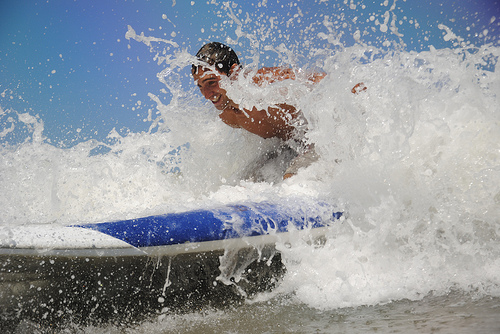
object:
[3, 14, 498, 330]
water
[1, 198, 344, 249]
board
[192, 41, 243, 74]
hair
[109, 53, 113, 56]
drop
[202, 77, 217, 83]
eyebrow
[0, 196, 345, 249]
surfboard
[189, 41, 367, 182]
man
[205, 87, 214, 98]
nose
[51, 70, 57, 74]
water drop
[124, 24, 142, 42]
drop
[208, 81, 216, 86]
eye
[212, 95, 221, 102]
teeth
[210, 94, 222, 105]
man's mouth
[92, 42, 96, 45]
drop